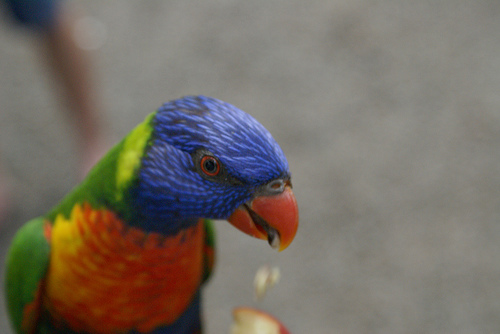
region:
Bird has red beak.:
[252, 203, 311, 250]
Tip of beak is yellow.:
[270, 231, 311, 281]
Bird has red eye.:
[198, 153, 236, 177]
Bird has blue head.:
[212, 105, 266, 155]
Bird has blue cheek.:
[158, 179, 214, 211]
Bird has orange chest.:
[91, 237, 179, 294]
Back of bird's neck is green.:
[78, 127, 148, 192]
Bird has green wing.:
[14, 220, 71, 290]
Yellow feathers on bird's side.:
[52, 210, 92, 315]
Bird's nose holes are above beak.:
[264, 170, 308, 196]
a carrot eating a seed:
[16, 87, 345, 331]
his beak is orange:
[237, 193, 295, 252]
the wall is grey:
[2, 2, 496, 327]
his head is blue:
[138, 88, 288, 235]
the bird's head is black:
[128, 89, 288, 234]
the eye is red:
[198, 149, 222, 179]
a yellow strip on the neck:
[115, 112, 151, 198]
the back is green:
[35, 140, 112, 222]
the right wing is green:
[0, 209, 55, 314]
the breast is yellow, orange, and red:
[42, 209, 204, 332]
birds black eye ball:
[198, 152, 225, 176]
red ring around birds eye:
[196, 146, 223, 178]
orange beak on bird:
[233, 180, 308, 250]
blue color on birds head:
[151, 83, 269, 219]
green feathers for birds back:
[51, 110, 152, 210]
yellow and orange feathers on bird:
[50, 219, 210, 316]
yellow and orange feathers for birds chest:
[51, 229, 193, 324]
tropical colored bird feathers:
[6, 88, 336, 330]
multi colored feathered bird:
[2, 94, 334, 332]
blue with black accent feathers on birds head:
[143, 75, 314, 252]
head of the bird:
[93, 80, 353, 302]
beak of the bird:
[227, 186, 312, 256]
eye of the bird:
[190, 138, 240, 184]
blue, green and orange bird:
[8, 76, 286, 307]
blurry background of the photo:
[364, 60, 471, 169]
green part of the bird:
[1, 213, 56, 300]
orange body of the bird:
[78, 246, 190, 313]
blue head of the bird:
[188, 94, 258, 144]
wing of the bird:
[3, 225, 70, 303]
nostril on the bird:
[256, 170, 291, 203]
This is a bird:
[68, 14, 273, 329]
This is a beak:
[233, 144, 290, 271]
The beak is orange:
[244, 199, 338, 299]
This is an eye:
[174, 121, 251, 217]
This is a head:
[131, 98, 346, 273]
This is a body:
[48, 233, 222, 308]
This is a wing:
[5, 229, 60, 294]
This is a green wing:
[10, 233, 51, 295]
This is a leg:
[43, 44, 208, 127]